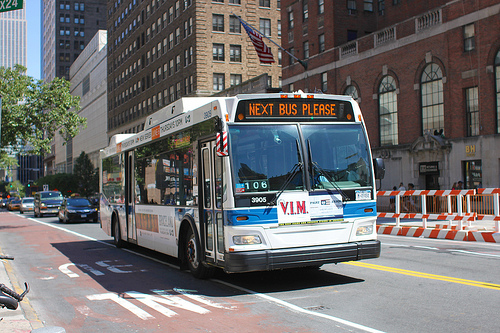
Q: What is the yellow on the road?
A: Paint.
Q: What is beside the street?
A: Roadblocks.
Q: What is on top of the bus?
A: Sign.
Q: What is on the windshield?
A: Windshield wipers.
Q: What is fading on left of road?
A: Paint.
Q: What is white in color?
A: The bus.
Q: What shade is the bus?
A: White.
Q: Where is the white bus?
A: On the street.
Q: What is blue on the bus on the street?
A: A stripe.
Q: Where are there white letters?
A: On the street.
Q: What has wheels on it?
A: Bus on the street.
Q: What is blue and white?
A: The bus paint.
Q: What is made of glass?
A: Windshield.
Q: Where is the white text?
A: On the street.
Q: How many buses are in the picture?
A: One.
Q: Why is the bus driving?
A: The bus is full.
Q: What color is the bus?
A: White.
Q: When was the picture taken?
A: During the day.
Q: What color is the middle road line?
A: Yellow.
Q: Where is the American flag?
A: Hanging on the building.